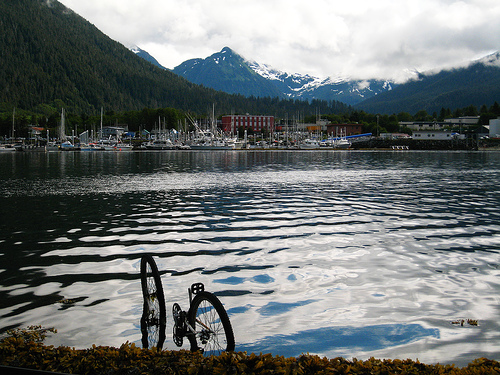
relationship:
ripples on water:
[223, 243, 260, 278] [263, 246, 495, 367]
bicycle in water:
[137, 250, 235, 355] [0, 144, 498, 370]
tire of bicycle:
[136, 254, 168, 347] [137, 250, 235, 355]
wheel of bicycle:
[186, 290, 235, 353] [137, 250, 235, 355]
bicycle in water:
[137, 255, 235, 355] [0, 144, 498, 370]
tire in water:
[123, 254, 175, 360] [190, 182, 483, 295]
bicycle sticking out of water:
[137, 255, 235, 355] [303, 176, 451, 293]